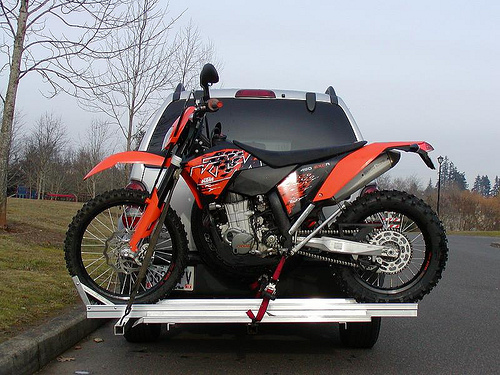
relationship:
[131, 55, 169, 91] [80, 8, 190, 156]
branch of tree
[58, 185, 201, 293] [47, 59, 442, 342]
wheel of motorcycle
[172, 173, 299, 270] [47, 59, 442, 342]
engine of motorcycle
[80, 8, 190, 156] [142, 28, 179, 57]
tree with no leaves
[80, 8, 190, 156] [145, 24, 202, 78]
tree with no leaves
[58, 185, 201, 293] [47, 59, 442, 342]
tire of motorcycle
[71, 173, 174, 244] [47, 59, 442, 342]
tire of motorcycle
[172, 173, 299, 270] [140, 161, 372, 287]
engine of bike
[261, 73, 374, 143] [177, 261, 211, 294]
suv has plate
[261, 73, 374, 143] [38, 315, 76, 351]
suv next to curb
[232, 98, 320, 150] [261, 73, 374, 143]
window of suv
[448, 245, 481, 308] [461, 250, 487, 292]
street has asphalt